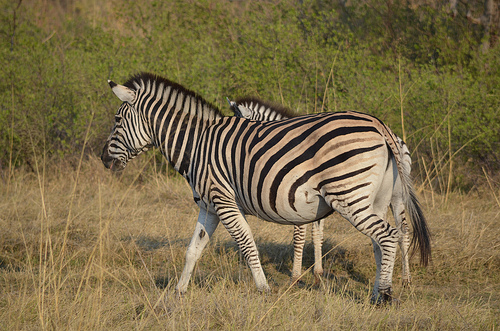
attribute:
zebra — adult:
[81, 60, 434, 304]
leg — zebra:
[214, 189, 288, 316]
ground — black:
[306, 207, 326, 248]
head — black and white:
[97, 65, 165, 174]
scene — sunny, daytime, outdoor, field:
[13, 20, 481, 316]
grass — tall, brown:
[9, 168, 174, 306]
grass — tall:
[289, 243, 381, 323]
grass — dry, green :
[0, 145, 499, 329]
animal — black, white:
[98, 75, 425, 301]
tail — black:
[398, 167, 449, 273]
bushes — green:
[40, 16, 497, 94]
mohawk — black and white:
[103, 64, 251, 123]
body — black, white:
[95, 63, 435, 311]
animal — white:
[228, 92, 412, 291]